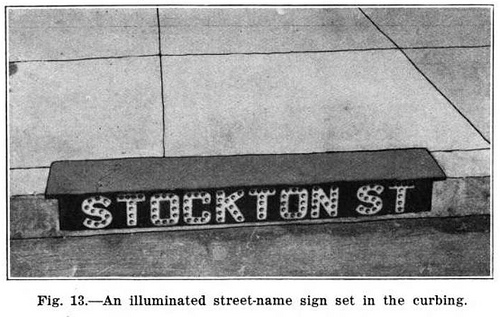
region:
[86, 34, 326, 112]
this is the ground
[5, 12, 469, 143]
the ground is big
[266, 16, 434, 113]
the ground is grey in color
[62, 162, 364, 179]
the area is black in color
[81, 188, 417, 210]
there are writings on the ground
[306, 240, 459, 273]
this is the road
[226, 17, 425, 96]
this is a pavement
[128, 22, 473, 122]
the ground has some dividing lines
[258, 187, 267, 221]
there are some dots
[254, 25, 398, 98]
nothing on the pavement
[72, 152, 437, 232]
sign says stockton st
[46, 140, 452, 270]
the sign is black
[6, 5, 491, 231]
the ground is made of squares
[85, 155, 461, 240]
the sign is illuminated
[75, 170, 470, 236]
the sign is of a street name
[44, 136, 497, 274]
the sign is on the edge of a curb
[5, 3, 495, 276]
the picture is in black and white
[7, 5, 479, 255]
the picture is a drawing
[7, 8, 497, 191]
the lines on the sidewalk are black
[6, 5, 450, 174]
no one is walking on the sidewalk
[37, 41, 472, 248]
A black and white photo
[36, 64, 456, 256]
A street name on a curb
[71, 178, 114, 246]
The letter "S" on a sign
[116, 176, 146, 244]
The letter "T" on a sign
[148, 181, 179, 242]
The letter "O" on a sign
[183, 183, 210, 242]
The letter "C" on a sign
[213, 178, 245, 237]
The letter "K" on a sign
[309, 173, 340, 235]
The letter "N" on a sign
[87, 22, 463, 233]
A sidewalk and curb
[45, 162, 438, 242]
An illuminated sign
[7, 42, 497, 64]
cut in sidewalk pavement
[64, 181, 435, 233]
Stockton street name sign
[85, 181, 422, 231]
light bulbs in street sign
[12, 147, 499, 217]
curbing edge of sidewalk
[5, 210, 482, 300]
pavement beyond curb edge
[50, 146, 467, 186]
top of street sign box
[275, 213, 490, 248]
stain on pavement below sign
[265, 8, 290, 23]
something on sidewalk at top of picture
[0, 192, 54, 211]
crack in sidewalk curbing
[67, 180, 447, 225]
illuminated portion of sign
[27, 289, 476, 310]
the caption to a photo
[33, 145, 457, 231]
an illuminated street sign set in the curbing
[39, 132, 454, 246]
a street sign for Stockton Street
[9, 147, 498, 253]
the curb of a sidewalk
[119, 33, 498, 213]
a square of sidewalk concrete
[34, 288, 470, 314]
A caption describing the photo above it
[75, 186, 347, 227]
Illuminated lettering in a street sign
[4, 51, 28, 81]
A stain on the sidewalk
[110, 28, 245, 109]
Lines between squares of concrete on the sidewalk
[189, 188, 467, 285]
A street surfaced in asphalt